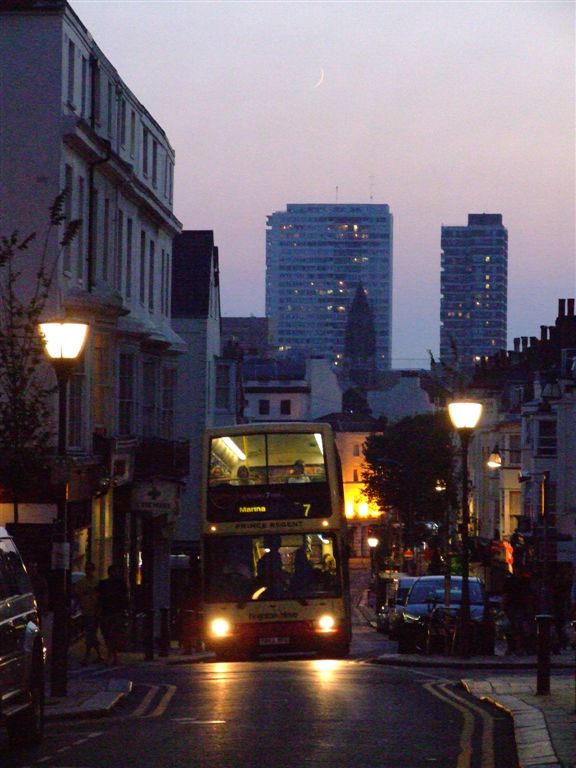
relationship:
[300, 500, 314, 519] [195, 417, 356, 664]
number 7 written on bus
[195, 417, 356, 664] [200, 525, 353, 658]
bus has bottom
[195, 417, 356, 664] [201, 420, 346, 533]
bus has top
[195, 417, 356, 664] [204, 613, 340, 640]
bus has headlights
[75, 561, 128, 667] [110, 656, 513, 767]
people are across street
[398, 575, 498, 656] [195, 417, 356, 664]
car parked near bus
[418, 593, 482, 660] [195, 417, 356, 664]
bikes parked near bus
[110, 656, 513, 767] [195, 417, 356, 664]
street in front of bus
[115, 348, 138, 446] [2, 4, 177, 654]
window on building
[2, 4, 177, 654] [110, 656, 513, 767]
building on street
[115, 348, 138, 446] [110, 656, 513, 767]
window facing street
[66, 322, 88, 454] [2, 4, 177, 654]
window on building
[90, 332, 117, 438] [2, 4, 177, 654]
window on building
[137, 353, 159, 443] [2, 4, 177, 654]
window on building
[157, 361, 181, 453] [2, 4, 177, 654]
window on building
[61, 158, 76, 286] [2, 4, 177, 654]
window on building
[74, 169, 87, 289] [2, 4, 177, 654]
window on building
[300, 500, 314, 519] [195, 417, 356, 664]
number 7 on bus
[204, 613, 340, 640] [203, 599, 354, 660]
headlights are on front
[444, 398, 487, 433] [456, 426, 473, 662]
lamp on lightpost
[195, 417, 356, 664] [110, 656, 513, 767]
double decker on road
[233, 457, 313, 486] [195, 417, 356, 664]
people on bus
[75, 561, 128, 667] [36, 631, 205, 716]
people on sidewalk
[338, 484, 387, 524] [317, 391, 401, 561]
lights are on building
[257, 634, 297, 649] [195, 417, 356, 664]
license plate on front of bus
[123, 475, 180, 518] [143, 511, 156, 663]
sign on post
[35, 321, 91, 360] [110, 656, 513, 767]
light on street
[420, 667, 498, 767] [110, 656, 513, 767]
lines are painted on street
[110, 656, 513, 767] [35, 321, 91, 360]
street has light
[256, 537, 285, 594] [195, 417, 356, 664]
person standing on bus